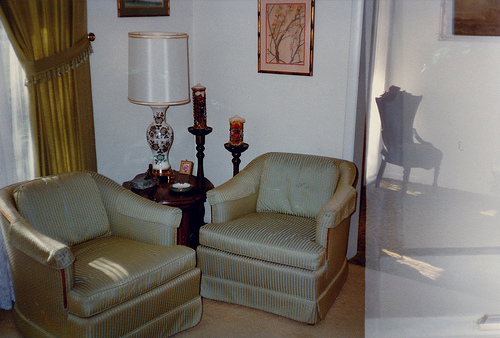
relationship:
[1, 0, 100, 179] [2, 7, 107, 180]
curtains are over a curtain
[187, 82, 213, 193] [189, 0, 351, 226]
candle near wall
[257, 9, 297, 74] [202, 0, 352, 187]
picture hanging on wall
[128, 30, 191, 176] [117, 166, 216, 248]
lamp on table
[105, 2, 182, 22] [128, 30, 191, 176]
picture over lamp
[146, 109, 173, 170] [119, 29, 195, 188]
floral pattern on lamp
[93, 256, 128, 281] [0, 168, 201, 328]
sunlight on chair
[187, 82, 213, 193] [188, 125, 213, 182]
candle on stand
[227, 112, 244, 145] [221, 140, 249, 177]
candle on stand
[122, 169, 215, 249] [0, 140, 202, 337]
side table beside chair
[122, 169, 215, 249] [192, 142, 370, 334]
side table beside chair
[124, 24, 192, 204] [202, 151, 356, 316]
lamp beside chair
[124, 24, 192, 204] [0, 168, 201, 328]
lamp beside chair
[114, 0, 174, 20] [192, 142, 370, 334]
art beside chair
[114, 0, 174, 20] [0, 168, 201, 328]
art beside chair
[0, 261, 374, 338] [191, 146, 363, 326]
carpet under chair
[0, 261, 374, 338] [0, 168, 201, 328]
carpet under chair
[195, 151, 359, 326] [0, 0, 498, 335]
chair in room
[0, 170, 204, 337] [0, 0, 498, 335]
chair in room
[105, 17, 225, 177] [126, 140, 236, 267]
lampshade on table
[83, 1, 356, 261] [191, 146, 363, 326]
wall behind chair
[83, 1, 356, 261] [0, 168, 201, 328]
wall behind chair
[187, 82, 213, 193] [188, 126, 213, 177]
candle on stand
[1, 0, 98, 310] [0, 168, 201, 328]
curtains behind chair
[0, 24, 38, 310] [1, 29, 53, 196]
sheer on window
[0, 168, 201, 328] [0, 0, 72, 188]
chair next to window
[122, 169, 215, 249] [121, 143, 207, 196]
side table with items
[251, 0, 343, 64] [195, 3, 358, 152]
image on wall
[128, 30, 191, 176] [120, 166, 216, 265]
lamp on table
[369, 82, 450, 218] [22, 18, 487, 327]
chair in room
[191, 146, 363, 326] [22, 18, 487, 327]
chair in room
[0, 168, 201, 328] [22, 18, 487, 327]
chair in room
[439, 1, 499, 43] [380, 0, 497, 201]
image on wall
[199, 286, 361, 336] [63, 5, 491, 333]
carpet in room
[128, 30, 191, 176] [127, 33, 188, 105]
lamp has white shade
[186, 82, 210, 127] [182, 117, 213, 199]
candle on pillar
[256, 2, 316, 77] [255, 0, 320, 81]
pink art in frame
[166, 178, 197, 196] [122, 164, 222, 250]
ashtray on side table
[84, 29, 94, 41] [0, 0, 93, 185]
fastener for drapes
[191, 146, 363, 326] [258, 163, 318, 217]
chair covered in fabric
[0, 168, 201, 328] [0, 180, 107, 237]
chair covered in fabric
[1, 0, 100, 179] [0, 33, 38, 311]
curtains hanging on side of window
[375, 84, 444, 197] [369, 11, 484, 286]
chair in background